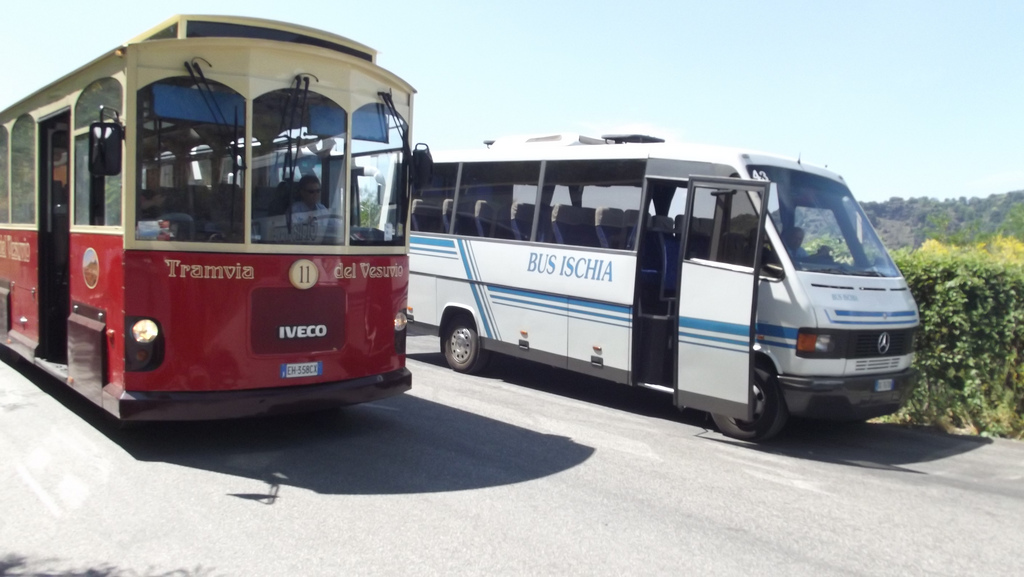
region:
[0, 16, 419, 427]
red and gold trolley next to bus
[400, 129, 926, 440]
white bus with blue stripes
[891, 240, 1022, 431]
green bushes behind the bus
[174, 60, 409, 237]
black windshield wipers on trolley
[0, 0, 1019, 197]
clear, light blue sky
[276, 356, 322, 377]
small white and blue trolley license plate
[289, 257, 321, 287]
trolley number in circle at the front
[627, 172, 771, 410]
large bus door is open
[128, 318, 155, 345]
small circular headlight on trolley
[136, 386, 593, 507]
trolley shadow on the road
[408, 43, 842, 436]
Windows on the bus.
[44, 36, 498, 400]
Windows on the trolley.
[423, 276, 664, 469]
Wheels on the bus.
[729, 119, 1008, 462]
Green bushes in the background.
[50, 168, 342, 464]
Lights on the trolley.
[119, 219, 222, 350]
Words on the trolley.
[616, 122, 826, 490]
Open door on the bus.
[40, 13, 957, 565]
vehicles on the road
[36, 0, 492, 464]
red bus on the road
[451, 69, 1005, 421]
white bus on the road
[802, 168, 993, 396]
green bushes in the background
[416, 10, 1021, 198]
clear blue sky in the background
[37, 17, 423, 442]
red and tan trolley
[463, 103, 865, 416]
blue and white van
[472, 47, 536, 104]
white clouds in blue sky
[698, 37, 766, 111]
white clouds in blue sky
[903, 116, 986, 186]
white clouds in blue sky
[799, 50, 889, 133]
white clouds in blue sky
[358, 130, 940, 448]
white bus with blue writing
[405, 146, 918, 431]
a large white van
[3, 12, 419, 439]
a white and red tram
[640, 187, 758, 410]
the door on the van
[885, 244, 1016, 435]
a bush behind the van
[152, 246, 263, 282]
writing on the tram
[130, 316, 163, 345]
a headlight on the tram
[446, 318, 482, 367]
the tire on the van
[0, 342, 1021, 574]
the black street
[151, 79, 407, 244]
the windshield on the tram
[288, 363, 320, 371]
the license plate on the tram